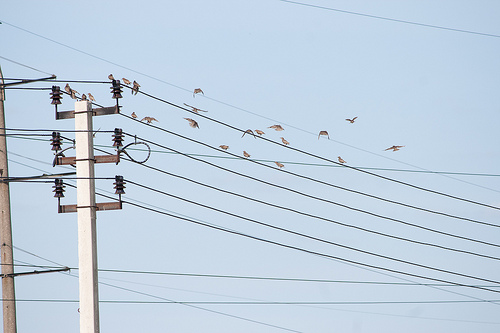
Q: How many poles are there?
A: Two.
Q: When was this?
A: Day time.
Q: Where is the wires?
A: On the poles.